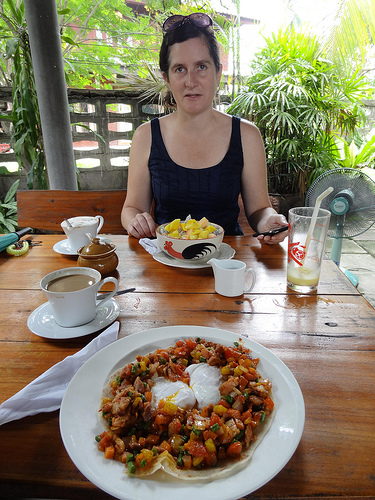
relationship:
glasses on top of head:
[159, 12, 212, 43] [154, 3, 234, 115]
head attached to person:
[154, 3, 234, 115] [120, 13, 290, 244]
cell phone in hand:
[251, 218, 306, 236] [247, 197, 293, 246]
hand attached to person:
[247, 197, 293, 246] [120, 13, 290, 244]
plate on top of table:
[134, 248, 219, 269] [290, 297, 371, 441]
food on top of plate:
[167, 214, 228, 241] [134, 248, 219, 269]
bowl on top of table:
[153, 225, 222, 262] [290, 297, 371, 441]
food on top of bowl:
[167, 214, 228, 241] [153, 225, 222, 262]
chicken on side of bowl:
[146, 241, 221, 262] [153, 225, 222, 262]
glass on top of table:
[288, 200, 322, 299] [290, 297, 371, 441]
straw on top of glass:
[315, 192, 333, 215] [288, 200, 322, 299]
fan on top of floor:
[315, 151, 368, 249] [325, 220, 375, 309]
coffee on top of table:
[45, 275, 98, 323] [290, 297, 371, 441]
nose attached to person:
[178, 77, 198, 89] [120, 13, 290, 244]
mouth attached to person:
[168, 90, 204, 102] [120, 13, 290, 244]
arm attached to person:
[124, 128, 160, 231] [120, 13, 290, 244]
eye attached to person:
[190, 60, 209, 79] [120, 13, 290, 244]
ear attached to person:
[218, 64, 232, 83] [120, 13, 290, 244]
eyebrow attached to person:
[169, 56, 186, 67] [120, 13, 290, 244]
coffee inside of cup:
[45, 275, 98, 323] [50, 303, 118, 332]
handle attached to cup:
[92, 265, 118, 310] [50, 303, 118, 332]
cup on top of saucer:
[50, 303, 118, 332] [47, 323, 96, 343]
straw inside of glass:
[315, 192, 333, 215] [288, 200, 322, 299]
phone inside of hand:
[255, 224, 292, 240] [247, 197, 293, 246]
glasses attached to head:
[158, 12, 211, 43] [154, 3, 234, 115]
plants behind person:
[66, 23, 129, 82] [168, 128, 265, 140]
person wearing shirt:
[168, 128, 265, 140] [138, 181, 262, 197]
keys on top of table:
[1, 237, 44, 254] [290, 297, 371, 441]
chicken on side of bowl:
[161, 240, 220, 262] [153, 225, 222, 262]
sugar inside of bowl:
[84, 242, 118, 269] [153, 225, 222, 262]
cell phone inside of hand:
[245, 219, 311, 240] [247, 197, 293, 246]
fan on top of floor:
[315, 151, 368, 249] [351, 245, 365, 281]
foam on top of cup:
[95, 213, 107, 230] [50, 303, 118, 332]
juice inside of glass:
[287, 269, 317, 284] [288, 200, 322, 299]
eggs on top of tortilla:
[171, 223, 187, 229] [105, 325, 250, 438]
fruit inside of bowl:
[164, 221, 185, 245] [153, 225, 222, 262]